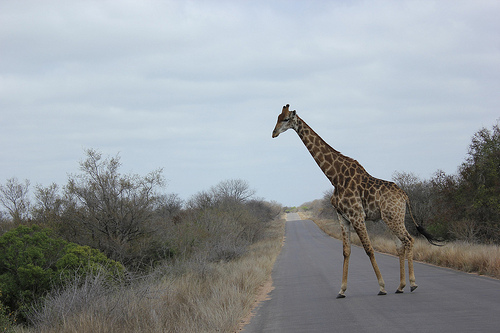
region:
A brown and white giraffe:
[270, 100, 454, 297]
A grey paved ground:
[284, 301, 352, 323]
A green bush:
[0, 226, 130, 323]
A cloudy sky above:
[64, 21, 261, 101]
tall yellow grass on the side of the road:
[442, 251, 487, 265]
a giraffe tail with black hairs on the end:
[405, 197, 451, 246]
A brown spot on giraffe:
[336, 173, 347, 186]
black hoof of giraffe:
[336, 291, 347, 301]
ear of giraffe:
[289, 109, 298, 116]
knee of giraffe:
[341, 246, 352, 261]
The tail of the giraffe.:
[403, 196, 443, 246]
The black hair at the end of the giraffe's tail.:
[417, 217, 447, 254]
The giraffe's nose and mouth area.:
[269, 127, 281, 139]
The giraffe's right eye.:
[282, 113, 292, 123]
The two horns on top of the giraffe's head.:
[281, 102, 289, 111]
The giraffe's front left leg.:
[336, 213, 346, 304]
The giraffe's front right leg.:
[350, 210, 392, 307]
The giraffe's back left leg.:
[390, 238, 407, 295]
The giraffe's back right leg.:
[406, 220, 420, 291]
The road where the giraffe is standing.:
[283, 260, 476, 297]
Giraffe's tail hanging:
[396, 192, 449, 248]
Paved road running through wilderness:
[264, 216, 492, 331]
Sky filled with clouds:
[3, 3, 497, 206]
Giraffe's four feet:
[331, 280, 425, 297]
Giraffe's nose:
[272, 130, 278, 136]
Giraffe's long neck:
[288, 110, 352, 180]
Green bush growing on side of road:
[0, 224, 136, 316]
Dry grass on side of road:
[45, 262, 267, 331]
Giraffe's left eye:
[277, 117, 294, 123]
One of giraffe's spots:
[322, 164, 337, 178]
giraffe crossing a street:
[251, 100, 461, 327]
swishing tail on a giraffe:
[401, 190, 452, 250]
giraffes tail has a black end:
[414, 217, 449, 248]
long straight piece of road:
[231, 202, 498, 331]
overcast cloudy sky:
[3, 3, 499, 218]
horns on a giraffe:
[277, 101, 293, 113]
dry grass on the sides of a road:
[61, 200, 494, 331]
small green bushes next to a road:
[1, 221, 135, 327]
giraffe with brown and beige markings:
[269, 100, 454, 301]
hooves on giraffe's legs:
[330, 277, 423, 302]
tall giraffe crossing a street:
[264, 76, 451, 307]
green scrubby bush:
[12, 229, 97, 285]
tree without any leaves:
[69, 139, 164, 231]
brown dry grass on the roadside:
[125, 278, 232, 332]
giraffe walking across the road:
[242, 67, 459, 318]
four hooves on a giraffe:
[329, 275, 440, 307]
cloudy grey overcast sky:
[65, 38, 187, 153]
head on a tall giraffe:
[265, 96, 308, 146]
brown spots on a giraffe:
[309, 135, 366, 191]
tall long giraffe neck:
[289, 112, 347, 184]